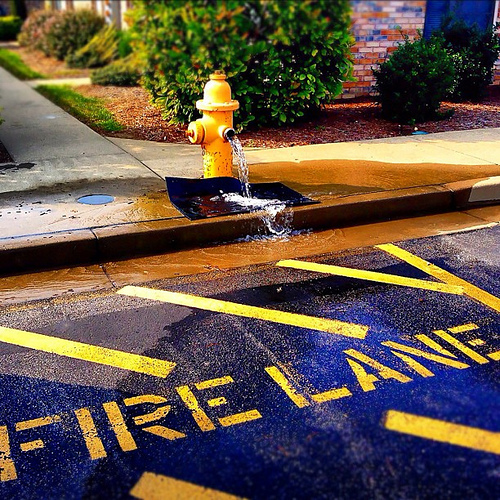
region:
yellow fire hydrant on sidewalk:
[182, 62, 244, 182]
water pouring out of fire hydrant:
[228, 136, 253, 196]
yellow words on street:
[1, 315, 498, 490]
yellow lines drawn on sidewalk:
[110, 255, 471, 342]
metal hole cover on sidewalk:
[67, 183, 121, 213]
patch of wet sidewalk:
[84, 210, 164, 250]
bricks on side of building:
[362, 6, 389, 41]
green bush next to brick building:
[364, 19, 467, 128]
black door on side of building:
[422, 0, 497, 55]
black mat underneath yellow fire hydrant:
[157, 164, 321, 233]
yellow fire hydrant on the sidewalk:
[176, 69, 265, 195]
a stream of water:
[227, 137, 255, 190]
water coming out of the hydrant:
[178, 59, 262, 186]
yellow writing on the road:
[0, 320, 499, 483]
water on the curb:
[4, 199, 494, 304]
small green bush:
[370, 32, 462, 125]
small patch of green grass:
[36, 83, 128, 133]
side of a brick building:
[317, 0, 437, 104]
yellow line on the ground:
[369, 400, 498, 463]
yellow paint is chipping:
[0, 447, 15, 474]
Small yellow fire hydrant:
[188, 68, 245, 176]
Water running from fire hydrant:
[230, 128, 257, 195]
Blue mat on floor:
[166, 173, 323, 221]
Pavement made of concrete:
[2, 84, 499, 256]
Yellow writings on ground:
[0, 330, 497, 482]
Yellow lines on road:
[1, 251, 498, 376]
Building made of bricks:
[337, 0, 429, 99]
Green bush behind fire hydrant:
[127, 2, 347, 129]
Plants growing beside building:
[18, 0, 143, 83]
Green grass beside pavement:
[0, 43, 117, 126]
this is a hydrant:
[191, 65, 238, 185]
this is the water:
[226, 134, 249, 172]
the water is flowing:
[234, 137, 256, 182]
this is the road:
[263, 285, 418, 461]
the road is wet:
[225, 250, 408, 440]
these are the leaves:
[260, 7, 338, 100]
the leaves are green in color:
[255, 8, 323, 89]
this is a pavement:
[26, 109, 61, 155]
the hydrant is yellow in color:
[197, 71, 230, 146]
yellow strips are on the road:
[314, 315, 439, 405]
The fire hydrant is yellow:
[186, 70, 233, 176]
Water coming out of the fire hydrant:
[185, 71, 247, 191]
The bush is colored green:
[376, 40, 451, 115]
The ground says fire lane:
[0, 312, 496, 472]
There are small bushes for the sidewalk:
[0, 35, 130, 154]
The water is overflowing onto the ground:
[170, 70, 309, 245]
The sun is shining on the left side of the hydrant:
[184, 70, 238, 187]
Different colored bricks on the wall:
[340, 2, 423, 41]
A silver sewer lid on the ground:
[77, 191, 114, 204]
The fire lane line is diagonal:
[116, 285, 373, 342]